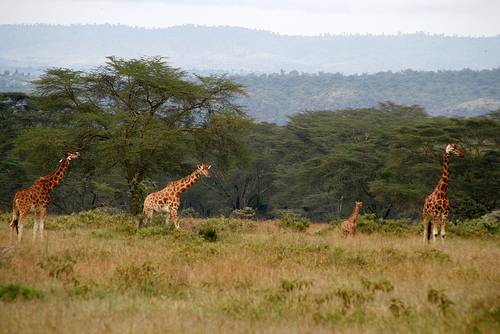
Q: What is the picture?
A: Giraffe.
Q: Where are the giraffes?
A: Field.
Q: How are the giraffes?
A: Standing.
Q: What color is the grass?
A: Brown and green.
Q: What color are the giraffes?
A: Brown.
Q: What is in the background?
A: Mountains.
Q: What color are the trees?
A: Green.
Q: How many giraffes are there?
A: Four.